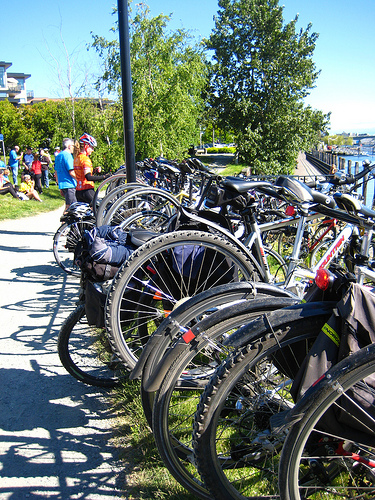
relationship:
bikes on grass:
[54, 170, 374, 491] [76, 205, 371, 497]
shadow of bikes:
[1, 227, 110, 500] [54, 170, 374, 491]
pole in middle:
[108, 0, 148, 191] [93, 2, 238, 163]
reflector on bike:
[176, 326, 201, 347] [130, 195, 374, 495]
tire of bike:
[134, 300, 297, 491] [130, 195, 374, 495]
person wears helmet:
[68, 130, 111, 199] [74, 129, 104, 150]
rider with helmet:
[68, 130, 111, 199] [74, 129, 104, 150]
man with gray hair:
[45, 132, 82, 219] [56, 134, 84, 159]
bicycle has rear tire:
[89, 184, 374, 404] [93, 214, 268, 401]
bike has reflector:
[130, 195, 374, 495] [176, 326, 201, 347]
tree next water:
[202, 2, 345, 184] [331, 148, 374, 181]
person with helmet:
[68, 130, 111, 199] [74, 129, 104, 150]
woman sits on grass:
[10, 166, 44, 207] [3, 185, 64, 219]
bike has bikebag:
[130, 195, 374, 495] [261, 278, 374, 447]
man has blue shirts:
[45, 132, 82, 219] [50, 145, 78, 193]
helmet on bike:
[56, 198, 101, 231] [43, 188, 130, 290]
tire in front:
[134, 300, 297, 491] [98, 234, 274, 399]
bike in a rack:
[54, 170, 374, 491] [207, 159, 374, 258]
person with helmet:
[71, 130, 114, 206] [74, 129, 104, 150]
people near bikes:
[2, 136, 57, 206] [54, 170, 374, 491]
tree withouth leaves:
[202, 2, 345, 184] [93, 2, 238, 163]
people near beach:
[2, 136, 57, 206] [305, 130, 374, 210]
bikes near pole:
[54, 170, 374, 491] [108, 0, 148, 191]